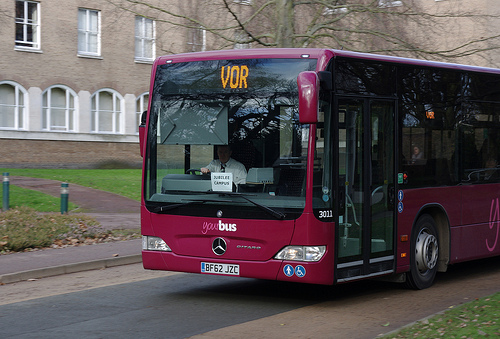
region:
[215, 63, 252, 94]
Orange and black bus sign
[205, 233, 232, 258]
Black and silver Mercedes logo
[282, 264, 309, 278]
Two blue and white circle signs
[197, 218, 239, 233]
Pink and white bus sign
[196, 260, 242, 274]
Blue and white license plate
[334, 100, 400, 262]
Black and glass doors to the bus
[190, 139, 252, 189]
Bus driver behind the wheel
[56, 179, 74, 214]
Green lamp post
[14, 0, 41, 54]
Open window in the building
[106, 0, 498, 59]
Tree without leaves behind the bus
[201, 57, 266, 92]
A orange lighted sign on a bus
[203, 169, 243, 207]
A black and white sign on a bus window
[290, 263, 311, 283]
A blue handicap sign on a bus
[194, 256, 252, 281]
A black and white license plate on a bus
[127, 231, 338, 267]
Front head lights on a purple bus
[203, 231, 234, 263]
A mercedes logo on the front of a bus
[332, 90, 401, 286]
Glass front does on a bus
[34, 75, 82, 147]
White window on a building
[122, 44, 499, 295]
City bus driving down the road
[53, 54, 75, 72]
Tan brick on the side of a building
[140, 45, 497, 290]
a red bus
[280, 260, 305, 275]
two round blue and white stickers on bus front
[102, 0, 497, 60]
leafless tree behind the bus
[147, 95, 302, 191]
front windshield of the bus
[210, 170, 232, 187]
the white sign in front of the bus driver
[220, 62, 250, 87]
orange letters on front of the bus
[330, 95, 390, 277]
door on the side of the bus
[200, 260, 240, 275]
license plate on front of the bus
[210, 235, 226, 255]
round Mercedes logo above license plate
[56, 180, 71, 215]
the green light post closest to the bus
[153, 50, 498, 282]
Bus is large and red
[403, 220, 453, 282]
Front left tire is black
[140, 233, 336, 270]
headlights of vehicle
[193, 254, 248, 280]
License plate is European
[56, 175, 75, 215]
Green post in background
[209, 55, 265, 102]
Says VOR on electronic sign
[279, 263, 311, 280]
Has disability option for people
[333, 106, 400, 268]
Double doors can open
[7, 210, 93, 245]
Leaves behind bus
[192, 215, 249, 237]
Says youbus on front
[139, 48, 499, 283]
wine bus on street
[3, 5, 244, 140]
white windows on bricked building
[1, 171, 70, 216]
two small green poles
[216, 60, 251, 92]
orange letters on electronic screen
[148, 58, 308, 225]
big windshield of big wine bus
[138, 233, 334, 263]
two white front lights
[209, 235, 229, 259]
black and gray metal mercedes benz symbol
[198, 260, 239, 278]
black blue and white license plate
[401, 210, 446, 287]
big black front left wheel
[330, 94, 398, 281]
big black doors of big bus